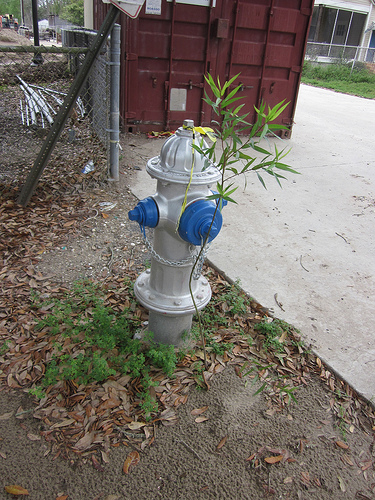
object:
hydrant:
[127, 119, 226, 361]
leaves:
[121, 448, 140, 477]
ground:
[0, 189, 374, 499]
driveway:
[118, 82, 374, 410]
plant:
[188, 71, 301, 373]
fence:
[0, 22, 121, 188]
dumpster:
[93, 0, 315, 140]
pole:
[108, 23, 121, 184]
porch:
[301, 1, 374, 72]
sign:
[108, 1, 147, 20]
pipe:
[15, 7, 121, 211]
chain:
[191, 232, 213, 280]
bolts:
[173, 297, 183, 308]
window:
[340, 13, 367, 65]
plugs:
[126, 196, 159, 229]